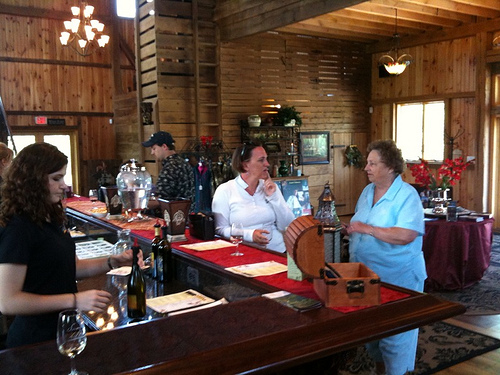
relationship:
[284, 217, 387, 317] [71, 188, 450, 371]
box on counter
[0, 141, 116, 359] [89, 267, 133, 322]
lady making a drink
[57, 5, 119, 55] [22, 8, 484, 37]
chandelier on ceiling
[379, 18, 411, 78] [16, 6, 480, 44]
light on ceiling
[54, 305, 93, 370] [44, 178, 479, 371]
glass on counter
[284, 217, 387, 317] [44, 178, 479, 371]
box on counter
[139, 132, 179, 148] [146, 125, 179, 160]
cap on head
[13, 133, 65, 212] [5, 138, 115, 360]
hair of a lady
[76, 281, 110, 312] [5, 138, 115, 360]
hand of a lady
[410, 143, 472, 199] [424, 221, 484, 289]
flowers on table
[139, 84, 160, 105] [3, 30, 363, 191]
board on wall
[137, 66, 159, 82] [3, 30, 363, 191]
board on wall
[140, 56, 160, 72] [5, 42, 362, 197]
board on wall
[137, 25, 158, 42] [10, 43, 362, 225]
board on wall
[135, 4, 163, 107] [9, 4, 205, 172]
board on wall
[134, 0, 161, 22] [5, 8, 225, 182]
board on wall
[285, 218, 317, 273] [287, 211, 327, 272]
board on wall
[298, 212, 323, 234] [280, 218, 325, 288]
board on wall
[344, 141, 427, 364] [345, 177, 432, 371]
lady wearing light blue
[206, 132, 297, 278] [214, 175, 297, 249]
woman has shirt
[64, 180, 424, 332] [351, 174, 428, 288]
runner on shirt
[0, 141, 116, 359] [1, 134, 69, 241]
lady has hair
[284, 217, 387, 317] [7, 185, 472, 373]
box on counter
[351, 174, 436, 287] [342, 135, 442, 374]
shirt on woman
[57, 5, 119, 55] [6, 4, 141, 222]
chandelier in background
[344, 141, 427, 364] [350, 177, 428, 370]
lady wearing outfit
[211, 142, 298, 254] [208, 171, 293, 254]
woman wearing shirt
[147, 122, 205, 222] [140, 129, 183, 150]
man wearing hat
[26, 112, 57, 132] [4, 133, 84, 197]
sign hanging over door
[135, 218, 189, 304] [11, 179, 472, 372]
bottles behind bar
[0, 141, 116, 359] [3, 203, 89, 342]
lady wearing shirt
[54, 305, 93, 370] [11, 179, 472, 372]
glass sitting on bar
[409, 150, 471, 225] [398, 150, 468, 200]
vase with flowers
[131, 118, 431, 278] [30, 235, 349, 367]
people at bar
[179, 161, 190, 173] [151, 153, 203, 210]
pattern on shirt